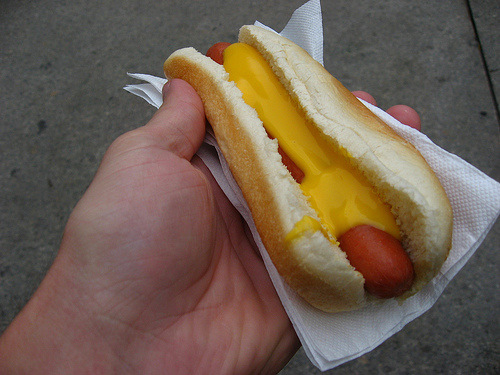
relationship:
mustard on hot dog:
[225, 38, 397, 231] [197, 28, 428, 303]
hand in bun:
[0, 75, 421, 375] [164, 17, 452, 319]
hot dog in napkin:
[199, 41, 416, 301] [365, 101, 485, 326]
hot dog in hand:
[199, 41, 416, 301] [63, 70, 425, 374]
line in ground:
[461, 2, 498, 127] [2, 3, 497, 373]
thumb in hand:
[153, 64, 215, 160] [85, 69, 435, 361]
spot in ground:
[35, 112, 52, 133] [13, 18, 103, 160]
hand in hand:
[0, 75, 421, 375] [63, 70, 425, 374]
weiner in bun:
[176, 24, 455, 307] [164, 17, 452, 319]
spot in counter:
[35, 119, 47, 136] [5, 4, 499, 369]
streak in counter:
[453, 2, 496, 121] [0, 2, 496, 104]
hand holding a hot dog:
[96, 64, 352, 274] [156, 21, 456, 316]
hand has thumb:
[127, 90, 297, 300] [151, 68, 204, 172]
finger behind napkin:
[386, 97, 416, 124] [119, 0, 499, 373]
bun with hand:
[164, 17, 452, 319] [0, 75, 421, 375]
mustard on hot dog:
[219, 41, 403, 246] [191, 32, 460, 305]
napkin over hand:
[119, 0, 499, 373] [63, 70, 425, 374]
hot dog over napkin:
[156, 21, 456, 316] [119, 0, 499, 373]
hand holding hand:
[0, 75, 421, 375] [0, 75, 421, 375]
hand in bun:
[0, 75, 421, 375] [324, 89, 446, 190]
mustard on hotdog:
[219, 41, 403, 246] [151, 19, 449, 302]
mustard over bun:
[219, 41, 403, 246] [258, 190, 338, 286]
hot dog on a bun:
[156, 21, 456, 316] [164, 17, 452, 319]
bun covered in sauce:
[164, 17, 452, 319] [219, 40, 398, 250]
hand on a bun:
[0, 75, 421, 375] [144, 22, 456, 324]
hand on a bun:
[0, 75, 421, 375] [163, 44, 362, 309]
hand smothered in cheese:
[0, 75, 421, 375] [221, 33, 406, 261]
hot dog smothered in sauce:
[156, 21, 456, 316] [219, 40, 398, 250]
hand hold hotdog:
[0, 75, 421, 375] [202, 30, 412, 293]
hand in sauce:
[0, 75, 421, 375] [219, 40, 398, 250]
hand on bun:
[0, 75, 421, 375] [163, 44, 362, 309]